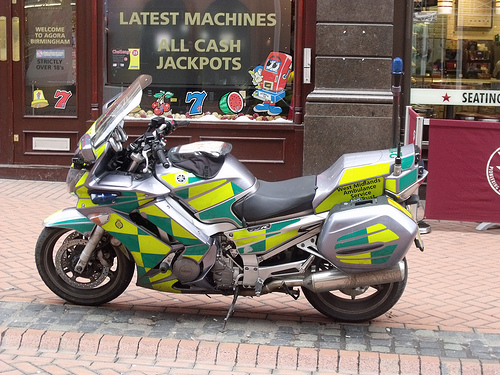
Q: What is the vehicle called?
A: Motorcycle.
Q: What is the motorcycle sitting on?
A: A street.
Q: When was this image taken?
A: Daytime.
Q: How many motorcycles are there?
A: One.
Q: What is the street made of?
A: Bricks.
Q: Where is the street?
A: Under the motorcycle.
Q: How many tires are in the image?
A: Two.